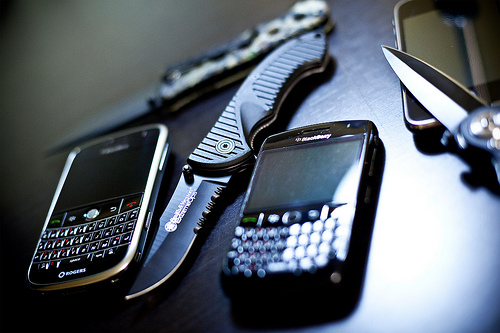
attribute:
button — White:
[62, 227, 70, 237]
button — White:
[85, 206, 99, 214]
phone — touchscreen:
[390, 0, 472, 131]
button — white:
[83, 221, 98, 233]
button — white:
[302, 220, 310, 234]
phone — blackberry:
[275, 150, 377, 318]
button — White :
[108, 221, 120, 240]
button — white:
[106, 214, 119, 229]